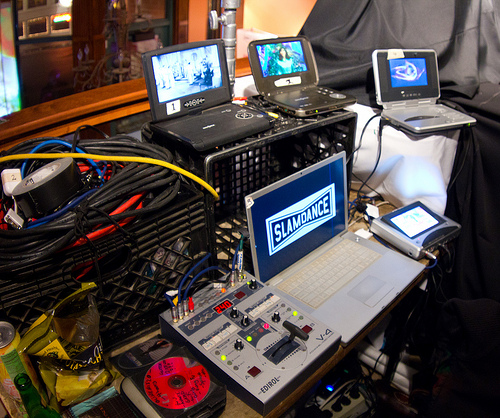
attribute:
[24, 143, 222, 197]
cable — yellow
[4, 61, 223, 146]
ledge — brown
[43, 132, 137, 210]
cable — black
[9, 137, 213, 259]
cable — black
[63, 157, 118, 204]
cable — blue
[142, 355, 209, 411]
compact disk — orange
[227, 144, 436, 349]
laptop — grey, big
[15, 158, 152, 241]
cable — green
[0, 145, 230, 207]
cable — yellow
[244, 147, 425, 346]
laptop — grey, small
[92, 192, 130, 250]
cable — orange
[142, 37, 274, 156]
laptop — small 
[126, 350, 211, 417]
disc — red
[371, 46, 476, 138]
laptop — small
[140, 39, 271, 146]
laptop — small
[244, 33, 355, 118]
laptop — small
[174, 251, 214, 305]
cable — green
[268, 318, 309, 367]
switch — black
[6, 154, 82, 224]
tape — black